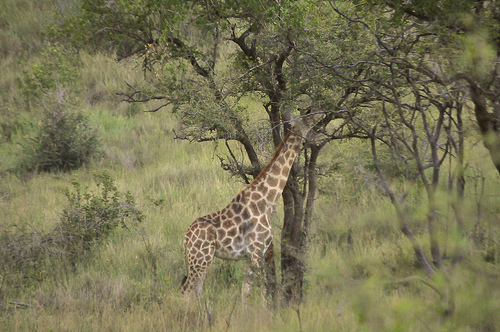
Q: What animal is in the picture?
A: Giraffe.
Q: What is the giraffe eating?
A: Leaves.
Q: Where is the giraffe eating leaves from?
A: Tree.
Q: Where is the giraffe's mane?
A: Neck.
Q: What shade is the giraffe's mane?
A: Brown.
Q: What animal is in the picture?
A: Giraffe.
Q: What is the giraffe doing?
A: Eating.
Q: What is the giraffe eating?
A: Leaves.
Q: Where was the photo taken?
A: Jungle.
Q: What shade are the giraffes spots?
A: Brown.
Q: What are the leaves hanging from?
A: Tree.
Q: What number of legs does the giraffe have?
A: 4.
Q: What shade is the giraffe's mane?
A: Brown.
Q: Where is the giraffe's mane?
A: Neck.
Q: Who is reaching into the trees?
A: A giraffe.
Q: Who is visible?
A: An animal.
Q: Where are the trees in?
A: The woods.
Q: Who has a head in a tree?
A: A giraffe.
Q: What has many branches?
A: A giraffe.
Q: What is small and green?
A: A bush.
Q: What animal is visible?
A: A giraffe.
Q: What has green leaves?
A: A tree.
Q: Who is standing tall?
A: A giraffe.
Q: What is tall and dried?
A: Grass.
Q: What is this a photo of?
A: A giraffe.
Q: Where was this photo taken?
A: Outside in the wilderness.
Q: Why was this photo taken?
A: To show the animal.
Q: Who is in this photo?
A: No one just a giraffe.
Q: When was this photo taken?
A: During the day.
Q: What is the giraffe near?
A: A tree.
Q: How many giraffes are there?
A: One.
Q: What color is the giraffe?
A: Brown and white.